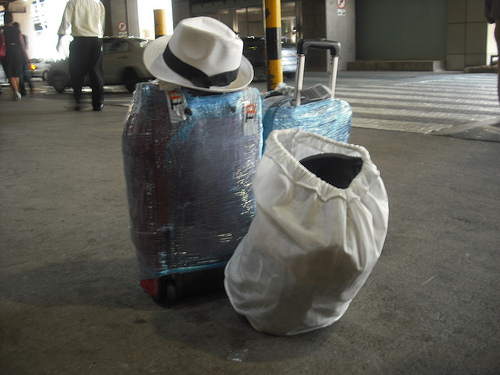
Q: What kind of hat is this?
A: Fedora.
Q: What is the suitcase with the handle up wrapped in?
A: Blue wrap.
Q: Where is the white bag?
A: On the floor.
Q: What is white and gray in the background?
A: The crosswalk is white and gray.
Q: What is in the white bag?
A: There are clothes.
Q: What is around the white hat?
A: A black ribbon.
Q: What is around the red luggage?
A: A plastic wrap.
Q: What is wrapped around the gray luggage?
A: A plastic wrap.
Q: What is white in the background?
A: A crosswalk.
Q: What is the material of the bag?
A: The bag is made of cloth.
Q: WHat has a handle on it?
A: The luggage.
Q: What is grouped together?
A: The luggage.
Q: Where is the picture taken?
A: An airport.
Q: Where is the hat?
A: On top of the suitcase.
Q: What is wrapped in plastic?
A: The luggage.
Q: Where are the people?
A: By the car.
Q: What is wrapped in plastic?
A: A suitcase.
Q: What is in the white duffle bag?
A: Clothing.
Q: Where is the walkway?
A: In a parking garage.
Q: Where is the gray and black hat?
A: On top of the suitcase.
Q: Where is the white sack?
A: By the suitcase.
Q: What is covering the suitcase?
A: Plastic.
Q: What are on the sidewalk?
A: Bags.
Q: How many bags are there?
A: Three.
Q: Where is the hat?
A: On the left bag.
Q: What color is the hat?
A: White.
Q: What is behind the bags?
A: Road.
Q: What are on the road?
A: Cars.